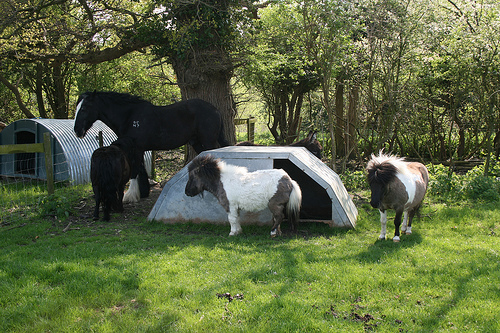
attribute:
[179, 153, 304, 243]
horse — standing, white, brown, small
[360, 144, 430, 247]
horse — white, brown, little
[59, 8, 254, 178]
tree — green, brown, large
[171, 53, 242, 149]
trunk — thick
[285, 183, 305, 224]
tail — white, gray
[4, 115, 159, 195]
shed — grey, metal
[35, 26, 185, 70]
limb — large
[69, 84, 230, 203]
horse — tall, black, large, white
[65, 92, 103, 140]
face — black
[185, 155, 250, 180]
mane — white, black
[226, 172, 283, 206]
back — white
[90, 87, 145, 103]
mane — black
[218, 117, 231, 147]
tail — black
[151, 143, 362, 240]
building — metal, little, white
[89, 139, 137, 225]
animal — brown, dark, little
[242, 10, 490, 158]
trees — brown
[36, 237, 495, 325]
grass — short, green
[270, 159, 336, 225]
door — open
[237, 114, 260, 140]
fence — brown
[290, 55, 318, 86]
leaves — green